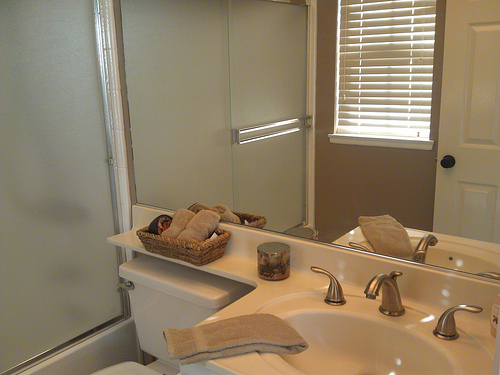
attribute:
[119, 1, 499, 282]
mirror — large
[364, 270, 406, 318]
faucet — brushed steel, silver, steel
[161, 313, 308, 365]
hand towel — grey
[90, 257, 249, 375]
toilet — white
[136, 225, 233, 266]
basket — woven, rectangular, brown, wicker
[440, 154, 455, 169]
door knob — black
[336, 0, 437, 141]
window — narrow, reflection, small, sunlit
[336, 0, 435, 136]
shutters — white, pulled down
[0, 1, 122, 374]
shower — glass, frosted, smoked glass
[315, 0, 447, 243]
reflection — dark grey wall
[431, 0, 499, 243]
door — white, reflection, open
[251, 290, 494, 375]
sink — oval shape, white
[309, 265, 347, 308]
handle — silver, brown, steel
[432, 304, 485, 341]
handle — silver, steel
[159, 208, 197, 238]
towel — taupe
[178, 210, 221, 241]
towel — taupe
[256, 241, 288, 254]
top — metal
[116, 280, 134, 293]
lever — silver